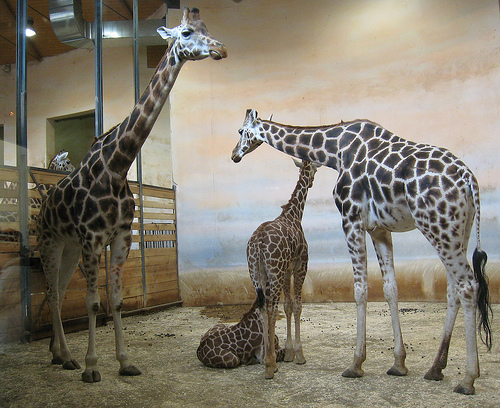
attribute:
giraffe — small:
[198, 282, 283, 368]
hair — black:
[467, 251, 497, 308]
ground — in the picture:
[421, 152, 452, 192]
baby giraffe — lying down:
[192, 297, 285, 371]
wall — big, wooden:
[319, 15, 465, 110]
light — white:
[81, 17, 139, 61]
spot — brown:
[393, 150, 418, 184]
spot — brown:
[333, 129, 360, 151]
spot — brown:
[310, 129, 326, 149]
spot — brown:
[78, 195, 100, 223]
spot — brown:
[99, 135, 116, 168]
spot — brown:
[125, 109, 149, 132]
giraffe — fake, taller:
[42, 8, 217, 379]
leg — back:
[418, 217, 498, 399]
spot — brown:
[61, 186, 81, 198]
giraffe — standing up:
[249, 160, 320, 378]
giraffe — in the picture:
[224, 107, 496, 392]